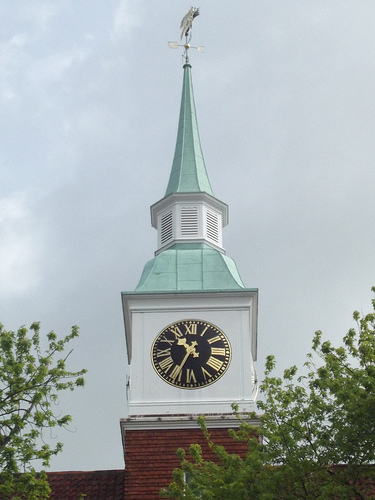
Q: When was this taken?
A: 10:34.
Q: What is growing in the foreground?
A: Trees.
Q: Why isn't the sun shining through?
A: Clouds.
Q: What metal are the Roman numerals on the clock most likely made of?
A: Brass.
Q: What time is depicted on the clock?
A: 10:35.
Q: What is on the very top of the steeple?
A: Weather vane.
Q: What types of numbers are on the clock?
A: Roman numerals.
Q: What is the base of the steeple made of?
A: Brick.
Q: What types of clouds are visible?
A: Cirrus.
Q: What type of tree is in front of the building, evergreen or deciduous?
A: Deciduous.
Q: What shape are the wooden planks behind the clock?
A: Rectangle.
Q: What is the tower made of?
A: Brick.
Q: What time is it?
A: 10:35.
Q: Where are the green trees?
A: In front of the tower.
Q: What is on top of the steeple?
A: A wind gauge.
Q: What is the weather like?
A: Overcast.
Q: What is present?
A: A tower.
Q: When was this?
A: Daytime.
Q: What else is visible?
A: Trees.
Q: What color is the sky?
A: Blue.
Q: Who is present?
A: Nobody.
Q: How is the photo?
A: Clear.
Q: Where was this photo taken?
A: Outside building.